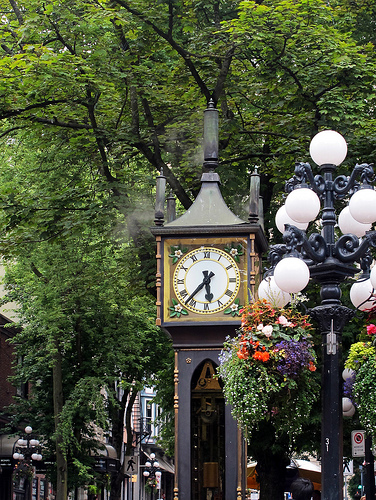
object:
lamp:
[257, 129, 375, 498]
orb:
[308, 128, 348, 166]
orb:
[284, 187, 322, 223]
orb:
[348, 187, 375, 225]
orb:
[272, 255, 310, 293]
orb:
[349, 276, 375, 312]